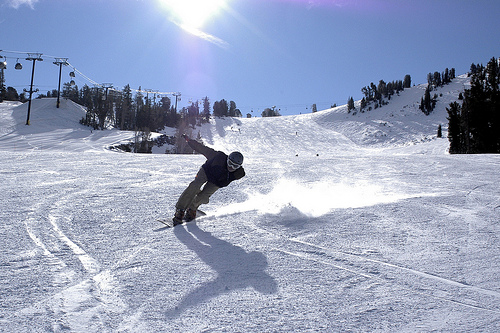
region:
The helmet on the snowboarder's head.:
[227, 145, 242, 163]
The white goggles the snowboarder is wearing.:
[225, 151, 237, 166]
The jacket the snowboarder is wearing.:
[205, 140, 235, 195]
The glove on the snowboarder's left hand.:
[180, 130, 190, 142]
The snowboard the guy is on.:
[158, 206, 204, 226]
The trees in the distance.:
[60, 73, 277, 127]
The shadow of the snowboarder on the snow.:
[166, 214, 278, 316]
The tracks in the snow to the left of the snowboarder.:
[20, 183, 114, 318]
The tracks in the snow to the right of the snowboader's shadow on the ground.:
[275, 226, 486, 321]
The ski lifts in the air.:
[2, 44, 79, 89]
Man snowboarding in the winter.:
[122, 83, 345, 262]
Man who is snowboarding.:
[135, 92, 293, 260]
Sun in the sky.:
[148, 1, 300, 61]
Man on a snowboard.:
[129, 95, 328, 255]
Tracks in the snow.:
[32, 163, 166, 328]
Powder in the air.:
[226, 158, 426, 238]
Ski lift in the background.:
[15, 42, 117, 149]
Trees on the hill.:
[335, 61, 460, 146]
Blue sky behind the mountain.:
[128, 25, 303, 116]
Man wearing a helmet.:
[227, 128, 244, 185]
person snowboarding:
[130, 107, 280, 262]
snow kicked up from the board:
[244, 171, 380, 230]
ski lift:
[0, 41, 179, 103]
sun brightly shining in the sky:
[153, 2, 239, 32]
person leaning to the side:
[134, 118, 264, 238]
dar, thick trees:
[443, 56, 499, 158]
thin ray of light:
[222, 3, 285, 49]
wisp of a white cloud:
[7, 0, 42, 13]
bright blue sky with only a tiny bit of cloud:
[2, 2, 499, 109]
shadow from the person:
[167, 221, 299, 323]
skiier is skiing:
[168, 128, 254, 224]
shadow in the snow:
[175, 225, 297, 315]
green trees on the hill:
[351, 84, 394, 107]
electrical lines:
[74, 73, 106, 86]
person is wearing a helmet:
[227, 150, 244, 163]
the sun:
[164, 3, 229, 28]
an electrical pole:
[27, 72, 34, 126]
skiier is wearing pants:
[180, 178, 210, 204]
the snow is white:
[31, 150, 144, 238]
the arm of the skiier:
[180, 130, 219, 157]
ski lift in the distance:
[0, 50, 186, 132]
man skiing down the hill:
[153, 128, 277, 240]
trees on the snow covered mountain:
[8, 44, 498, 157]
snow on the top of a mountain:
[4, 71, 498, 331]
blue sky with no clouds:
[0, 0, 499, 119]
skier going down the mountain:
[140, 125, 266, 236]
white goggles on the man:
[222, 158, 242, 174]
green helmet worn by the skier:
[226, 150, 248, 165]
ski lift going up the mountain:
[1, 50, 191, 137]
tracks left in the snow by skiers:
[11, 152, 498, 329]